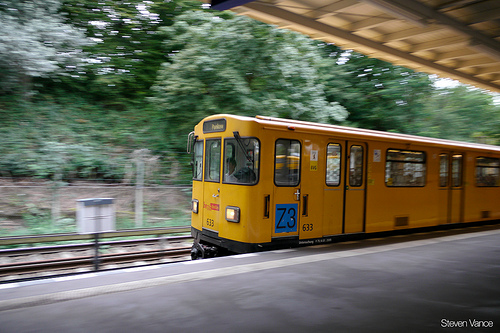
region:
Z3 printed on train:
[273, 207, 298, 230]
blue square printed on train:
[273, 202, 298, 233]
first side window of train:
[272, 137, 301, 186]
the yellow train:
[193, 113, 497, 238]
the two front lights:
[190, 197, 241, 218]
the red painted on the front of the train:
[201, 198, 221, 213]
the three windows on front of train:
[192, 140, 259, 182]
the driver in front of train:
[223, 158, 238, 183]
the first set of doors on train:
[323, 140, 366, 232]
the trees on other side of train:
[34, 15, 193, 147]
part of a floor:
[388, 273, 413, 295]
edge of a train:
[243, 180, 263, 249]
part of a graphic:
[453, 311, 490, 331]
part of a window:
[224, 148, 253, 175]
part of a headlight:
[214, 192, 246, 236]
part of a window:
[279, 142, 291, 159]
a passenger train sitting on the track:
[183, 107, 498, 252]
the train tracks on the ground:
[3, 223, 191, 270]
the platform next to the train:
[0, 220, 497, 331]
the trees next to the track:
[0, 0, 488, 222]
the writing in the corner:
[438, 317, 495, 329]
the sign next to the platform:
[72, 195, 119, 271]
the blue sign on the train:
[273, 198, 294, 230]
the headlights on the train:
[186, 195, 241, 226]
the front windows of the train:
[188, 139, 252, 182]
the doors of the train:
[323, 142, 366, 232]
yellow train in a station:
[175, 97, 498, 265]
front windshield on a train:
[182, 131, 263, 193]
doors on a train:
[318, 133, 373, 243]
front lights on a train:
[221, 199, 244, 227]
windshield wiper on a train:
[229, 126, 258, 179]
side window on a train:
[378, 141, 433, 192]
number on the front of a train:
[201, 213, 218, 232]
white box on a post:
[64, 191, 125, 243]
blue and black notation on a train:
[269, 197, 302, 239]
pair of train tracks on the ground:
[1, 233, 188, 275]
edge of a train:
[224, 135, 269, 216]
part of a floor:
[350, 265, 405, 321]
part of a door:
[271, 179, 296, 226]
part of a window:
[225, 130, 253, 163]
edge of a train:
[242, 160, 268, 219]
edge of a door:
[336, 166, 356, 209]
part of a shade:
[346, 262, 401, 302]